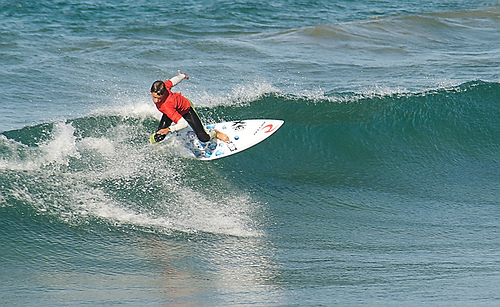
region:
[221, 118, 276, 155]
surfboard in the water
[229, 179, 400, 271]
water in the ocean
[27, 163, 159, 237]
waves on the water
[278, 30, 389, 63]
the water is calm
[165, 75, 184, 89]
arm of the man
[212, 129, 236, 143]
foot on the surfboard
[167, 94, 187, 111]
shirt on the man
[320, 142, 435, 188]
the wave is green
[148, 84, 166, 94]
cap on the man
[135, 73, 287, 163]
surfer riding a wave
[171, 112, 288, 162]
white surfboard on the water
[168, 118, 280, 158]
stickers and logos on white surfboard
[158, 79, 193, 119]
red shirt worn by surfer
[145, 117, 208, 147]
black wetsuit pants worn by surfer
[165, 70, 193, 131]
white sleeves of surfer's shirt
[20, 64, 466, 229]
white spray of the wave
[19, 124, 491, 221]
swell of the wave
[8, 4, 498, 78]
ocean waters behind wave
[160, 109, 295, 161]
surfboard coming out of the wave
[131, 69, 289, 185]
the boy is surfing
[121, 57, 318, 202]
the boy is surfing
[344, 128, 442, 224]
the water is green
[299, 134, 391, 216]
the water is green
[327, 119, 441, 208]
the water is green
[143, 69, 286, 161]
a man is on a surfboard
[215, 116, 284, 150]
nose of a surfboard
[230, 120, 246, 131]
a logo on a surfboard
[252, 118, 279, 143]
a logo on a surfboard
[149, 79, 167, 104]
head of a boy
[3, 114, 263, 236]
a wave is crashing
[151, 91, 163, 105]
face of a man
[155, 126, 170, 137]
a person's hand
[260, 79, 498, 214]
a wave that is about to crash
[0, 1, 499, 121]
choppy ocean water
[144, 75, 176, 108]
the head of a man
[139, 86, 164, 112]
the nose of a man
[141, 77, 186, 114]
the hair of a man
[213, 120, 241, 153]
the foot of a man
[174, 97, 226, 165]
the leg of a man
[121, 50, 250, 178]
a man in the water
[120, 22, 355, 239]
a wave in the ocean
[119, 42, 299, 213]
a surfboard in the water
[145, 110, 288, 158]
white surfboard in the water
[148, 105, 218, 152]
black colored pants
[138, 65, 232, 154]
person on a surfboard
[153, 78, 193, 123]
red colored tee shirt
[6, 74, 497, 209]
wave in the water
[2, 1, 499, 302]
body of green water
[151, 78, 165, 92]
brown hair on a surfer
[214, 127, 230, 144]
bare left foot on the board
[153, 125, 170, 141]
left hand of the surfer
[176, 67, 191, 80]
right hand of the surfer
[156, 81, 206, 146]
man usisng a black sport pants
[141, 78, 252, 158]
boy over the surfboard